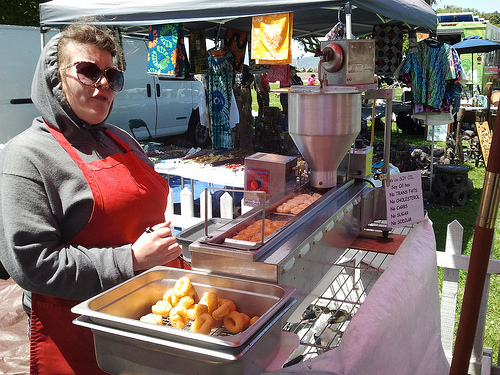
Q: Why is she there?
A: Selling mini donuts.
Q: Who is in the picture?
A: A woman.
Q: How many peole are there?
A: 1.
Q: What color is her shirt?
A: Gray.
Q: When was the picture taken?
A: In the daytime.